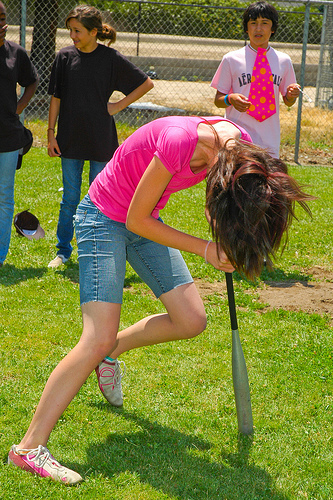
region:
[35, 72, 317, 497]
girl holding a bat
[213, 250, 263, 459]
the bat is silver and black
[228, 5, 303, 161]
boy wearing a tie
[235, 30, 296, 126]
the tie is pink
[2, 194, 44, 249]
cap on the ground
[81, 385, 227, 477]
shadow on the ground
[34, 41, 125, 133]
the t-shirt is black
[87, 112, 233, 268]
the shirt is pink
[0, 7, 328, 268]
people inside the fence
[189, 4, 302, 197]
the boy is watching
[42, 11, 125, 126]
the girl in black shirt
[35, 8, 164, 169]
the girl in black shirt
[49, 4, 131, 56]
a young girl with brown hair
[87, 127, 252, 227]
a young girl wearing a pink shirt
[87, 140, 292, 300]
a girl leaning over a baseball bat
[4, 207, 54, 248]
a black cap on the ground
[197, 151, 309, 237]
a girl with brown hair and red streaks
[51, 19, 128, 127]
a young girl wearing a black shirt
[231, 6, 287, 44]
a young boy with black hair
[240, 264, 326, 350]
a patch of dirt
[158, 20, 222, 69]
a chain link fence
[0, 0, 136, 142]
a young boy and girl standing next to each other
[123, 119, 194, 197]
young woman wearing pink shirt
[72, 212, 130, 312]
young woman wearing blue shorts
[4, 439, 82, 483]
young woman wearing pink shoe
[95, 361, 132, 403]
young woman wearing pink shoe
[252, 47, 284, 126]
young woman wearing pink and yellow tie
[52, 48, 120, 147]
young woman wearing black shirt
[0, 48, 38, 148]
young woman wearing black shirt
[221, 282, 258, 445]
young woman playing spinning game with bat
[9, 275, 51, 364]
green grass on field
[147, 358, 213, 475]
green grass on field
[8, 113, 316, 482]
Young girl spinning around a bat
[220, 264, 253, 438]
Silver and black bat held by spinning girl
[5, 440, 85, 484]
Pink and white shoe on young girl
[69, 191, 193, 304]
Jean shorts on young girl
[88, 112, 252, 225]
Pink shirt on young girl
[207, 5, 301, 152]
Boy watching young girl spinning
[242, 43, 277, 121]
Wide, purple and gold tie on young boy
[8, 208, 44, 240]
Black hat lying on grass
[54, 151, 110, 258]
Blue jeans on woman in background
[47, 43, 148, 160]
Black shirt on woman in background